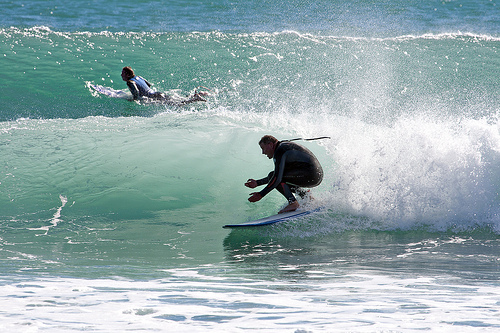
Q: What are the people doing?
A: Surfing.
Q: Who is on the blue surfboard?
A: The man.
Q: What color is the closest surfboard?
A: Blue.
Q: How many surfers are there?
A: Two.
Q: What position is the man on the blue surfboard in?
A: Crouch.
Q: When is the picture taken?
A: Day time.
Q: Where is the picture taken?
A: The beach.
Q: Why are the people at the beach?
A: Surfing.